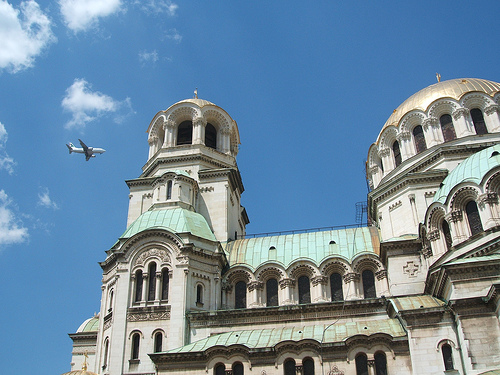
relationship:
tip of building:
[425, 67, 450, 87] [371, 91, 499, 305]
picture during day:
[52, 34, 459, 283] [6, 3, 432, 106]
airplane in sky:
[65, 137, 107, 162] [59, 2, 312, 90]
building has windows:
[371, 91, 499, 305] [218, 244, 425, 351]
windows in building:
[218, 244, 425, 351] [371, 91, 499, 305]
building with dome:
[371, 91, 499, 305] [392, 67, 498, 113]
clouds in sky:
[71, 78, 137, 115] [59, 2, 312, 90]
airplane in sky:
[14, 102, 162, 195] [59, 2, 312, 90]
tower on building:
[135, 102, 277, 253] [371, 91, 499, 305]